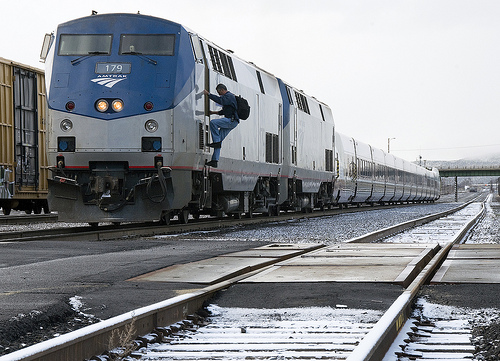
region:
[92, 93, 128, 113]
the headlights on a train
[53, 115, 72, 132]
the headlights on a train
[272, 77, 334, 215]
a blue train car on a track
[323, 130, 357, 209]
a train car on a track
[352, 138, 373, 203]
a train car on a track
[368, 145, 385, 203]
a train car on a track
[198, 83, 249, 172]
a man entering a train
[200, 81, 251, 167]
a man with a back pack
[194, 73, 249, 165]
train operator entering the train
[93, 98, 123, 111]
lights on the train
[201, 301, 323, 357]
snow on the train rails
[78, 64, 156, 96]
Amtrak train number 179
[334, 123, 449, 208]
passenger cars attached to the train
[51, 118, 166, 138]
headlights on a train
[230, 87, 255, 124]
man wearing a back pack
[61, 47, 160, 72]
windshield wipers on a train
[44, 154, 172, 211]
wires on the locomotive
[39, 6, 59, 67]
mirror on the train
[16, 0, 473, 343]
A train is moving through the city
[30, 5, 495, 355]
A person is climbing on the train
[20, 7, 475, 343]
A train is stopping for passengers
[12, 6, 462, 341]
A train has a powerful locomotive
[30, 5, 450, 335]
A training is pulling many cars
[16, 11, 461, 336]
A train is transporting many vacationers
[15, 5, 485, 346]
A train is stopping for more fuel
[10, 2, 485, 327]
A train is traveling in daytime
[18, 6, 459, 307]
A train is on the railroad tracks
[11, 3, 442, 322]
A train is stopped for repairs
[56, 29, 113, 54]
glass window on train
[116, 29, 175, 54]
glass window on train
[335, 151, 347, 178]
glass window on train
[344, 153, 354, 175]
glass window on train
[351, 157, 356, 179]
glass window on train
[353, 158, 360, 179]
glass window on train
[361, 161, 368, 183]
glass window on train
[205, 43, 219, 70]
glass window on train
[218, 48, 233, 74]
glass window on train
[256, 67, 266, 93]
glass window on train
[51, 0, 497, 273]
this is a train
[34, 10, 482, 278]
this is a passenger train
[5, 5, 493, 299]
this is an amtrak train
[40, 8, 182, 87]
front windows on train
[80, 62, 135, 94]
white decal on train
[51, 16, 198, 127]
blue upper half of train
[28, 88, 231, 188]
grey bottom of train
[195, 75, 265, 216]
a man climbing a ladder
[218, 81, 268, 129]
man wearing a backpack